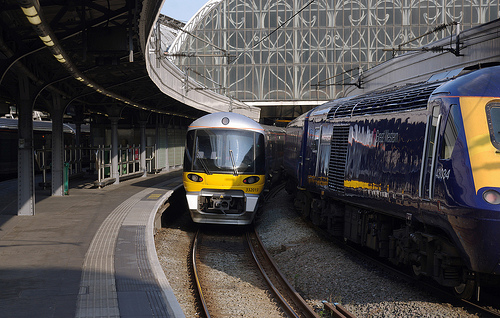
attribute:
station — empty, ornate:
[3, 96, 164, 300]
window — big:
[347, 106, 418, 193]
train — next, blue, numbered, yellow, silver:
[180, 113, 271, 216]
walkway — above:
[152, 34, 306, 119]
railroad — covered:
[204, 240, 310, 308]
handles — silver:
[421, 131, 451, 180]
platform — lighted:
[94, 159, 180, 316]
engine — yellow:
[169, 158, 326, 226]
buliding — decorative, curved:
[223, 20, 386, 94]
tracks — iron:
[190, 232, 391, 315]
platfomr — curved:
[85, 176, 200, 314]